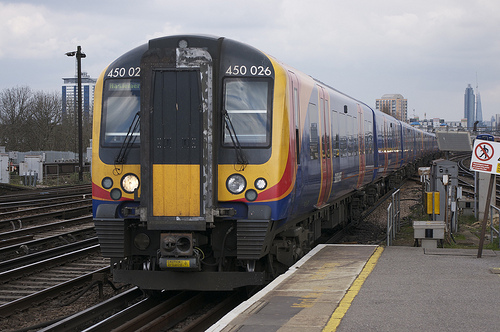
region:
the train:
[76, 44, 333, 325]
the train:
[91, 33, 275, 213]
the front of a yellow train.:
[88, 34, 287, 258]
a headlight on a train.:
[117, 160, 146, 201]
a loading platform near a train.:
[205, 240, 389, 330]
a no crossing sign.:
[467, 136, 498, 261]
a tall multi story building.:
[373, 89, 411, 121]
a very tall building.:
[454, 75, 487, 132]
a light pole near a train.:
[62, 30, 92, 190]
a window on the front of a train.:
[223, 76, 270, 158]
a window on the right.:
[88, 74, 147, 153]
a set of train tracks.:
[34, 281, 204, 329]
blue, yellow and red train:
[89, 30, 440, 294]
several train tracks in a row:
[4, 199, 91, 322]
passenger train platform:
[206, 246, 476, 324]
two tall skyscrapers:
[460, 70, 485, 137]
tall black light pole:
[64, 44, 90, 183]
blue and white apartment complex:
[60, 68, 95, 135]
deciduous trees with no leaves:
[6, 83, 61, 142]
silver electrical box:
[421, 155, 462, 235]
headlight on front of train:
[118, 171, 141, 194]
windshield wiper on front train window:
[111, 110, 143, 163]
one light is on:
[115, 177, 151, 210]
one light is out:
[223, 171, 266, 204]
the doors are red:
[305, 89, 337, 204]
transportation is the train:
[106, 47, 396, 249]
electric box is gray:
[425, 147, 487, 252]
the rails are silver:
[378, 182, 418, 253]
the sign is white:
[471, 133, 498, 184]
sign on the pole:
[471, 126, 498, 251]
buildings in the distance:
[373, 88, 488, 128]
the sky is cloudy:
[268, 2, 488, 117]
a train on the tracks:
[70, 9, 475, 311]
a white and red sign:
[457, 126, 498, 264]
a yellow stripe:
[320, 235, 394, 327]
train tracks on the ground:
[5, 204, 95, 308]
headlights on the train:
[94, 159, 279, 211]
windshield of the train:
[207, 62, 284, 164]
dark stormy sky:
[324, 26, 478, 103]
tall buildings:
[447, 68, 494, 145]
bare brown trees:
[0, 71, 70, 162]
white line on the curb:
[215, 233, 326, 330]